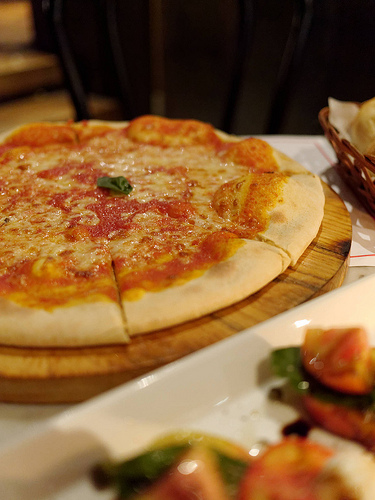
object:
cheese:
[198, 172, 212, 186]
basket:
[317, 98, 375, 207]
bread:
[326, 96, 375, 157]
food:
[300, 325, 375, 395]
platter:
[0, 176, 352, 404]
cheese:
[1, 135, 248, 295]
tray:
[0, 115, 353, 404]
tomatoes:
[133, 443, 224, 500]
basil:
[90, 347, 375, 500]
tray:
[0, 271, 375, 500]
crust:
[226, 162, 313, 239]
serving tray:
[0, 267, 375, 498]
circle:
[339, 239, 352, 257]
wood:
[1, 177, 352, 403]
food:
[0, 113, 325, 343]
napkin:
[329, 97, 375, 156]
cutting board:
[0, 178, 353, 404]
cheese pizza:
[177, 169, 323, 267]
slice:
[95, 195, 290, 334]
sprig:
[96, 176, 135, 196]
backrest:
[24, 0, 375, 117]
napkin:
[349, 240, 375, 267]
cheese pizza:
[169, 123, 211, 144]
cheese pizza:
[46, 274, 103, 300]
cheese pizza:
[38, 155, 67, 181]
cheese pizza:
[70, 219, 134, 249]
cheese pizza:
[170, 188, 205, 213]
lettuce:
[84, 423, 243, 492]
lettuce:
[255, 344, 309, 397]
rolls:
[327, 96, 374, 166]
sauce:
[101, 199, 152, 242]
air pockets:
[211, 173, 282, 229]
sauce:
[75, 172, 166, 239]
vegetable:
[97, 175, 132, 194]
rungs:
[75, 7, 317, 97]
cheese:
[6, 216, 55, 264]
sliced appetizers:
[146, 447, 224, 496]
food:
[326, 96, 375, 164]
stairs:
[27, 0, 153, 121]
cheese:
[163, 147, 189, 166]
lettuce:
[96, 176, 132, 195]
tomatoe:
[240, 436, 328, 498]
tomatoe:
[303, 324, 375, 397]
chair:
[29, 0, 325, 121]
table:
[254, 133, 375, 283]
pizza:
[0, 114, 326, 348]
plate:
[1, 274, 375, 497]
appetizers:
[85, 326, 375, 500]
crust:
[0, 238, 122, 332]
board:
[0, 177, 354, 404]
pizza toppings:
[0, 113, 325, 343]